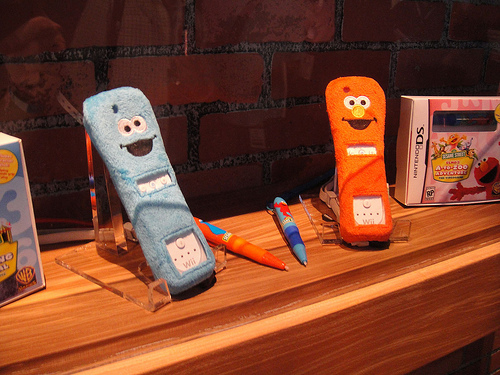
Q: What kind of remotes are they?
A: Wii.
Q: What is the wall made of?
A: Brick.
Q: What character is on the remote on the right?
A: Elmo.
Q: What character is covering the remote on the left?
A: Cookie Monster.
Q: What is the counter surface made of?
A: Wood.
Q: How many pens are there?
A: Two.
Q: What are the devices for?
A: Video game.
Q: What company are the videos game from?
A: Nintendo.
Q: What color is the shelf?
A: Brown.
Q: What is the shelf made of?
A: Wood.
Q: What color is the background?
A: Black.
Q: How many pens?
A: Two.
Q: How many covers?
A: Two.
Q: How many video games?
A: Two.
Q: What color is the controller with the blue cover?
A: White.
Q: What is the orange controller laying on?
A: Stand.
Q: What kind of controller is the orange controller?
A: Wii.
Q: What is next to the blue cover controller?
A: Pen.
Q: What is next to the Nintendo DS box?
A: Orange controller.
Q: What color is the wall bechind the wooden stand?
A: Red and black.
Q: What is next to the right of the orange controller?
A: Box.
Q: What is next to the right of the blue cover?
A: Pen.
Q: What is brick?
A: A wall.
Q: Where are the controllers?
A: On a shelf.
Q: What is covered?
A: The controllers.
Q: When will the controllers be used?
A: Soon.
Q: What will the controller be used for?
A: Gaming.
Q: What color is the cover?
A: Blue.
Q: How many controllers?
A: 2.